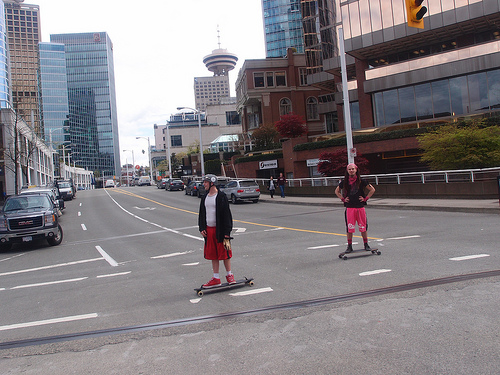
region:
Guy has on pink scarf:
[344, 174, 359, 185]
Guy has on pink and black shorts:
[340, 206, 370, 237]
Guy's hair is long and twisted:
[340, 165, 360, 187]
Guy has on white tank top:
[200, 192, 220, 224]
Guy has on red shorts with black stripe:
[197, 225, 232, 265]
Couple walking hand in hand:
[265, 170, 285, 195]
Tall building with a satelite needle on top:
[200, 20, 237, 75]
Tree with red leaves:
[270, 106, 305, 136]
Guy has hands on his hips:
[330, 160, 377, 250]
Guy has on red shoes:
[200, 273, 240, 288]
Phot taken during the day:
[12, 5, 490, 363]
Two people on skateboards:
[185, 149, 382, 303]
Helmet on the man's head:
[197, 175, 217, 190]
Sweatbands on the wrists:
[337, 194, 373, 204]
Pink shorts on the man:
[338, 203, 376, 235]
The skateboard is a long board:
[195, 275, 262, 295]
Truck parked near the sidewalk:
[3, 181, 73, 248]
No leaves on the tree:
[11, 110, 46, 167]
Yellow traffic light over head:
[400, 0, 430, 35]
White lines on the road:
[75, 210, 175, 257]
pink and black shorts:
[343, 205, 365, 235]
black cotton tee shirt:
[336, 175, 366, 202]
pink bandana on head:
[345, 160, 355, 167]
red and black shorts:
[200, 225, 225, 260]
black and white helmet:
[204, 173, 217, 185]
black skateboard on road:
[191, 276, 255, 291]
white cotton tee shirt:
[203, 192, 217, 227]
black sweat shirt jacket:
[195, 190, 235, 242]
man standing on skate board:
[333, 163, 385, 260]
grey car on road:
[222, 177, 261, 204]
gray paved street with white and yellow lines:
[5, 180, 493, 365]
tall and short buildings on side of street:
[146, 1, 482, 176]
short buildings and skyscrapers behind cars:
[0, 0, 120, 245]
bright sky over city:
[20, 0, 261, 172]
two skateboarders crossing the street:
[180, 155, 380, 296]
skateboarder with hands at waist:
[330, 157, 381, 258]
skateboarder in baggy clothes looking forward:
[183, 169, 258, 300]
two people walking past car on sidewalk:
[245, 165, 280, 195]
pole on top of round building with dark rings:
[196, 22, 240, 77]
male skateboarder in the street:
[178, 172, 265, 307]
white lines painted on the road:
[78, 218, 120, 280]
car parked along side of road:
[3, 179, 67, 263]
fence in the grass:
[377, 161, 495, 186]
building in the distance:
[46, 20, 121, 185]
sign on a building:
[252, 152, 284, 174]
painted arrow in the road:
[131, 200, 158, 214]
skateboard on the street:
[336, 242, 388, 267]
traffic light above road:
[398, 0, 435, 29]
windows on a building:
[371, 82, 491, 123]